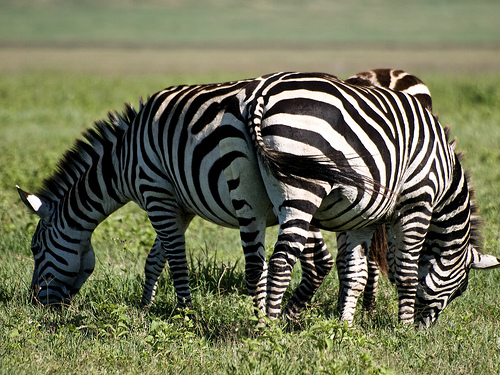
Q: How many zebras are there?
A: Two.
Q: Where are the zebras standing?
A: In the grass.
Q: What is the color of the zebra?
A: Black and White.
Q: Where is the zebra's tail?
A: At the end of his butt.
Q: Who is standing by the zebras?
A: Noone.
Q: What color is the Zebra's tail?
A: Black.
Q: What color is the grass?
A: Green.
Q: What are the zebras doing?
A: Eating grass.